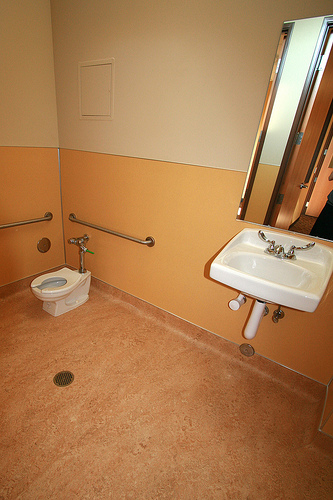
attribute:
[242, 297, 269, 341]
pipe — white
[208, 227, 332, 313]
sink — porcelain, white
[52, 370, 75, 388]
drain — brassy, silver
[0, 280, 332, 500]
floor — brown, sienna, tan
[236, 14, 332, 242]
mirror — shiny, big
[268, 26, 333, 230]
door — metal, small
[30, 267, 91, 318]
toilet — short, white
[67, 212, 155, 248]
railing — silver, here, metal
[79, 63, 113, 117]
door — white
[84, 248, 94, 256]
flush — green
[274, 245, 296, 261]
faucet — silver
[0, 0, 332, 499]
bathroom — clean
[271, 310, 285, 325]
valve — here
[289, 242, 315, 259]
handles — silver